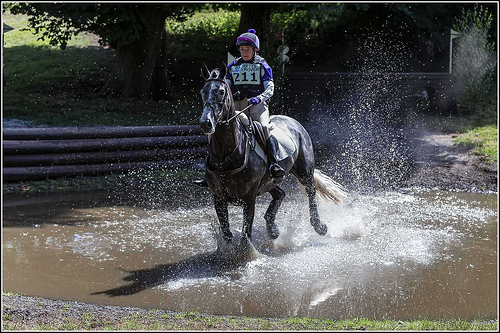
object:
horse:
[199, 61, 350, 248]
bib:
[225, 55, 274, 104]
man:
[194, 28, 286, 187]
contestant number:
[229, 63, 261, 85]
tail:
[313, 168, 350, 207]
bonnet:
[236, 29, 260, 52]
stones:
[5, 296, 146, 331]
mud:
[329, 270, 499, 317]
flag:
[449, 29, 461, 74]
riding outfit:
[223, 55, 274, 140]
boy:
[193, 29, 284, 188]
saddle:
[234, 110, 296, 163]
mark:
[201, 81, 217, 120]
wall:
[293, 82, 322, 109]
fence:
[3, 125, 210, 179]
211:
[233, 72, 257, 82]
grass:
[3, 292, 499, 330]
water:
[3, 58, 496, 319]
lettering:
[233, 72, 257, 82]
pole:
[449, 40, 452, 73]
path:
[400, 113, 498, 191]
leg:
[264, 185, 286, 239]